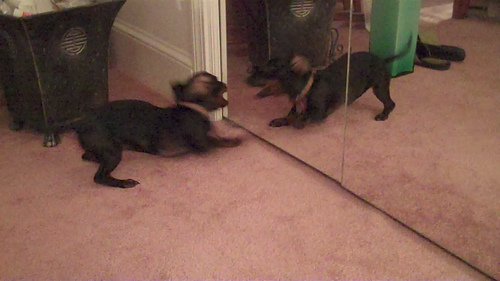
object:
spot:
[141, 263, 174, 280]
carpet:
[3, 65, 499, 280]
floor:
[3, 18, 496, 280]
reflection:
[243, 25, 404, 130]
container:
[367, 0, 421, 80]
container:
[0, 0, 127, 130]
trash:
[1, 0, 100, 21]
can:
[2, 0, 127, 148]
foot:
[39, 131, 63, 149]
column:
[363, 0, 426, 76]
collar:
[173, 98, 212, 118]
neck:
[176, 98, 213, 117]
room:
[0, 0, 495, 277]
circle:
[49, 20, 94, 58]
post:
[371, 16, 418, 71]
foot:
[101, 173, 141, 191]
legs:
[79, 135, 244, 195]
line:
[336, 117, 350, 174]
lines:
[284, 156, 466, 265]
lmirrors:
[342, 57, 451, 216]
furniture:
[4, 23, 113, 105]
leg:
[200, 132, 247, 149]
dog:
[68, 70, 250, 192]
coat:
[46, 71, 240, 188]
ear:
[191, 71, 215, 93]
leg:
[80, 129, 139, 190]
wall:
[0, 0, 499, 281]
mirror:
[223, 2, 493, 259]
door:
[0, 0, 488, 278]